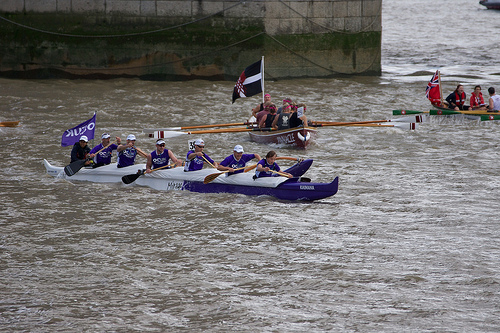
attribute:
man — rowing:
[221, 146, 259, 174]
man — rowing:
[184, 137, 215, 171]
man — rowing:
[146, 138, 184, 175]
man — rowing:
[117, 133, 148, 165]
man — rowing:
[94, 134, 117, 164]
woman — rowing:
[254, 149, 286, 177]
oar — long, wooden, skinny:
[151, 121, 253, 139]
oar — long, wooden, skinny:
[149, 118, 260, 128]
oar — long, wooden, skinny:
[311, 119, 416, 132]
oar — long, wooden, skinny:
[308, 116, 430, 128]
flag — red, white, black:
[231, 62, 263, 100]